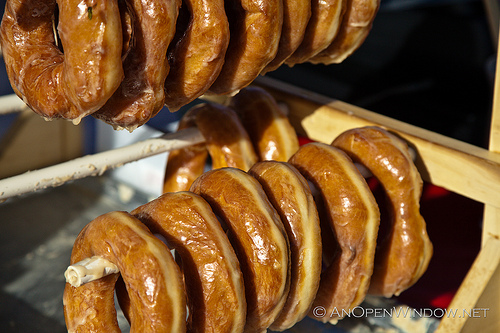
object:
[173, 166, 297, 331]
donut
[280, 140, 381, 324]
donut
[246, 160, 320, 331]
donut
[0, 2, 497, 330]
rack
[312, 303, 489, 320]
letters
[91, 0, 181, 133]
donut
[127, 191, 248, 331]
donut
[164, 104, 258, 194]
donut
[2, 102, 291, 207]
rod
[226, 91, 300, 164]
donut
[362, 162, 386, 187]
edge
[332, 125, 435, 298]
cake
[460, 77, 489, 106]
ground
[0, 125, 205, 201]
stick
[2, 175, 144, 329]
table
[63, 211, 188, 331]
donut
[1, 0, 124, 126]
donut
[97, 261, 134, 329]
hole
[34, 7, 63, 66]
hole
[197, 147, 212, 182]
hole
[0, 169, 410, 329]
gray surface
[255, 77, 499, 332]
box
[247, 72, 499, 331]
table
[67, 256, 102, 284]
stick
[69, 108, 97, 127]
glaze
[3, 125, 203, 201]
dowel